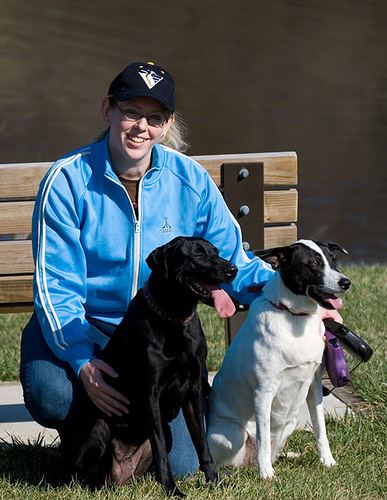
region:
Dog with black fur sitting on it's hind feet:
[142, 240, 226, 481]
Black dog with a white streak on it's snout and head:
[259, 240, 360, 315]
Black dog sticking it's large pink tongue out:
[147, 239, 239, 319]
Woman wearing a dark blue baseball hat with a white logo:
[97, 61, 172, 157]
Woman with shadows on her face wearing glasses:
[108, 93, 169, 165]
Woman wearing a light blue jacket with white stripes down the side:
[25, 70, 185, 364]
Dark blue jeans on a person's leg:
[18, 340, 76, 415]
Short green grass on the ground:
[286, 461, 385, 498]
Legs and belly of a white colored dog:
[248, 351, 336, 473]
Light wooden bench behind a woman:
[2, 159, 296, 261]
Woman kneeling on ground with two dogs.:
[32, 57, 373, 497]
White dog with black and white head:
[210, 234, 354, 481]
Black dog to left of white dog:
[62, 232, 237, 492]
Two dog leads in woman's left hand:
[322, 298, 369, 387]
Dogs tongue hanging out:
[209, 286, 236, 319]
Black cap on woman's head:
[106, 59, 176, 114]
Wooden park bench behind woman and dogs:
[0, 145, 300, 349]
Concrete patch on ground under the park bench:
[0, 370, 357, 440]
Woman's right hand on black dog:
[76, 355, 132, 419]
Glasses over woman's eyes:
[115, 103, 173, 125]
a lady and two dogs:
[52, 45, 357, 308]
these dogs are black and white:
[133, 213, 351, 438]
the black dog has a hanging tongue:
[110, 235, 234, 484]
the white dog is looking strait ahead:
[258, 232, 351, 437]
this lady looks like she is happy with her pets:
[77, 48, 207, 242]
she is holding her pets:
[58, 125, 291, 357]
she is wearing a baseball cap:
[102, 58, 184, 119]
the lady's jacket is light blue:
[39, 149, 316, 313]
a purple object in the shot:
[321, 326, 349, 398]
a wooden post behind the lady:
[6, 141, 302, 309]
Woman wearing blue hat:
[18, 60, 343, 482]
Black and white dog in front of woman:
[208, 235, 352, 485]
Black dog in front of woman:
[57, 236, 239, 498]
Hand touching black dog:
[79, 356, 132, 422]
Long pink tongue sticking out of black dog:
[207, 282, 236, 316]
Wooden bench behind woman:
[0, 151, 297, 310]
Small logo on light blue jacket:
[158, 211, 174, 234]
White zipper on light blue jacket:
[134, 219, 141, 233]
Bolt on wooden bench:
[237, 166, 248, 179]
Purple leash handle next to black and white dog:
[324, 327, 349, 387]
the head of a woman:
[97, 54, 180, 163]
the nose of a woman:
[130, 110, 149, 134]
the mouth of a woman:
[121, 130, 153, 148]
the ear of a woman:
[158, 110, 180, 139]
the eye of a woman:
[122, 105, 141, 119]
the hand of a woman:
[78, 352, 133, 425]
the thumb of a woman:
[93, 356, 121, 380]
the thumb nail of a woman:
[108, 368, 121, 379]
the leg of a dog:
[142, 387, 179, 485]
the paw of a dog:
[164, 480, 188, 498]